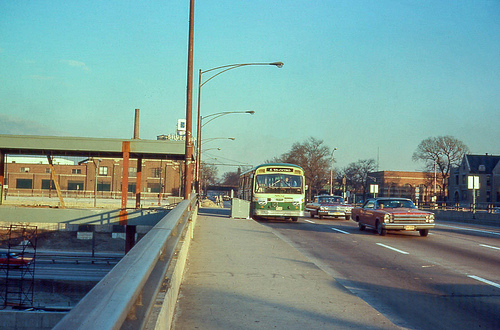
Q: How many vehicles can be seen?
A: 3.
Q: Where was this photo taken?
A: On a road.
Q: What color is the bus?
A: Green and yellow.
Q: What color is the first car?
A: It is red.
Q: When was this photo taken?
A: During the day.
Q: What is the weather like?
A: Clear and sunny.